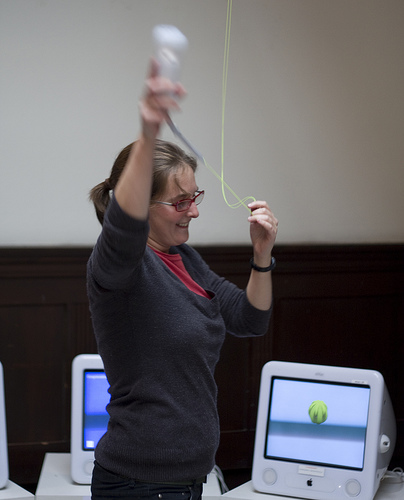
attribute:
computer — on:
[1, 348, 398, 499]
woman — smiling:
[84, 23, 302, 499]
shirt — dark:
[75, 195, 242, 489]